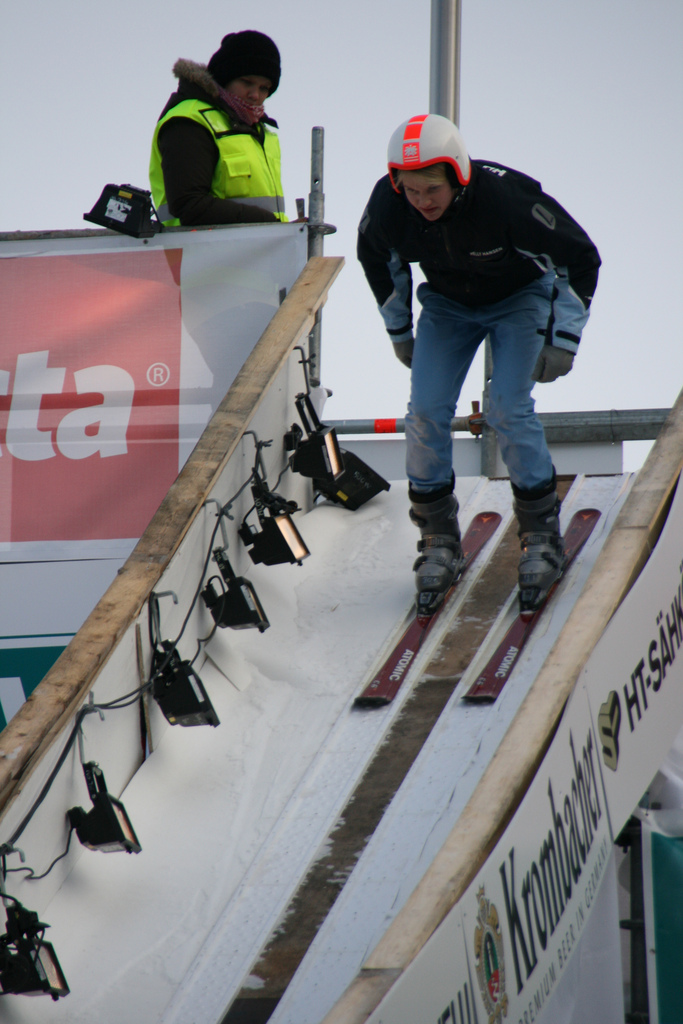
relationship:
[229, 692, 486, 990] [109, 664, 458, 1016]
tracks are in snow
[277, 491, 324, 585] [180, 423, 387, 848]
light on ramp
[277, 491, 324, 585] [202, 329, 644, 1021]
light on ramp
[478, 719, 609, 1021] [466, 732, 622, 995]
letters on sign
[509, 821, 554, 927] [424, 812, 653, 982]
letters on sign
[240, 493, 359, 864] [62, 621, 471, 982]
snow on slope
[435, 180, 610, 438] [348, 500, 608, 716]
man on skis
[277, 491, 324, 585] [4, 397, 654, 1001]
light on ramp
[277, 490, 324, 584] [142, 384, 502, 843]
light on ramp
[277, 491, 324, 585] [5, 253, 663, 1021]
light on ramp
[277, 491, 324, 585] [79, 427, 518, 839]
light on ramp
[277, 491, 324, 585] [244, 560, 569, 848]
light on ramp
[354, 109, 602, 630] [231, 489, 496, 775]
man on slope